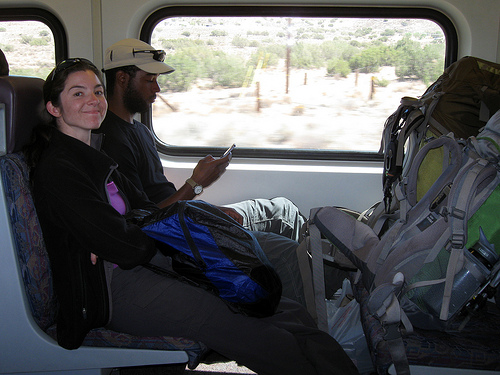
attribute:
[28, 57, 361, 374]
woman — smiling, lady, light skinned, traveling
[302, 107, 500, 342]
backpack — large, grey, silver, green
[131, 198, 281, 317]
bag — black, blue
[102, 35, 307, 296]
man — traveling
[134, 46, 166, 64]
sunglasses — black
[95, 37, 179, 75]
hat — cap, white, tan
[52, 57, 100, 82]
sunglasses — black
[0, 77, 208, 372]
seats — cushioned, cloth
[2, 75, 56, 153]
head rest — brown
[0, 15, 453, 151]
ground — desert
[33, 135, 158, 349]
shirt — black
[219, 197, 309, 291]
jeans — blue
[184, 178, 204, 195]
watch — wrist watch, tan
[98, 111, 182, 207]
shirt — black